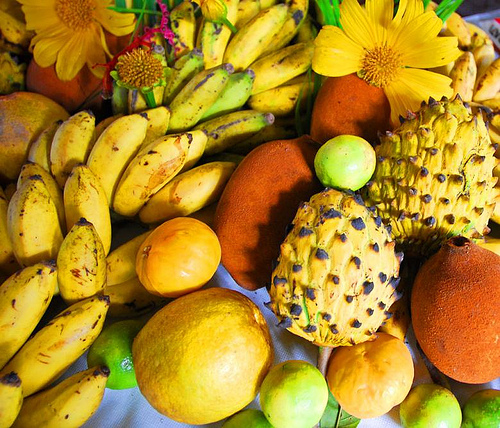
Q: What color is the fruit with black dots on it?
A: Yellow.